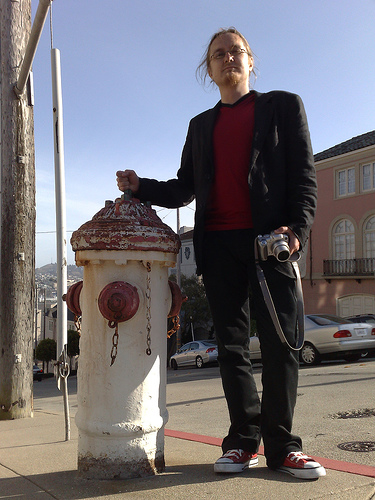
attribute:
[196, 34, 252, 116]
man — standing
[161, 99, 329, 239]
coat — black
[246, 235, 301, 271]
camera — silver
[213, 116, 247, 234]
shirt — red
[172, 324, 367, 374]
cars — parked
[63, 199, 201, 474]
hydrant — beige, white